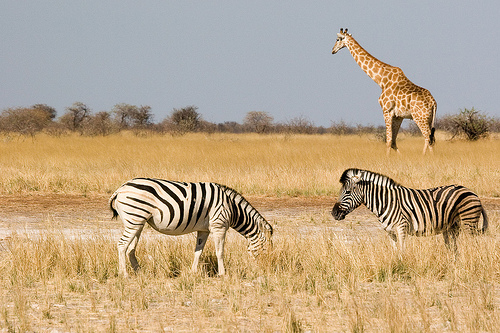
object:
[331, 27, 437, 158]
giraffe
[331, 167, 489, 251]
zebra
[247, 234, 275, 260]
head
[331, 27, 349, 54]
head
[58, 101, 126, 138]
tree line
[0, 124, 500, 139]
horizon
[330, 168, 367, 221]
head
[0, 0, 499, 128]
sky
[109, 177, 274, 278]
zebras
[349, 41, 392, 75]
neck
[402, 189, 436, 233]
stripes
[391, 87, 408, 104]
spots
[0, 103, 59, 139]
trees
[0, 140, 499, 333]
plain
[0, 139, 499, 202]
grass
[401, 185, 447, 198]
back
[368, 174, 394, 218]
neck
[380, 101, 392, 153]
leg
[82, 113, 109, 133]
branch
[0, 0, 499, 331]
field